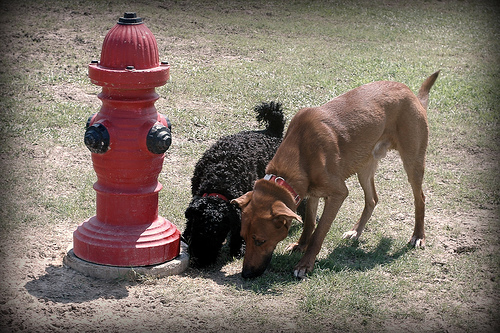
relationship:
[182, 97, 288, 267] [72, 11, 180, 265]
dog near hydrant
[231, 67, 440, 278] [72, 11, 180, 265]
dog near hydrant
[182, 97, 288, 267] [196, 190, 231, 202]
dog has collar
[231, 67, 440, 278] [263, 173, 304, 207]
dog has collar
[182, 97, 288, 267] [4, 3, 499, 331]
dog sniffing ground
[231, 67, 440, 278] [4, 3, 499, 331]
dog sniffing ground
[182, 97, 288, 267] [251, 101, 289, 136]
dog has tail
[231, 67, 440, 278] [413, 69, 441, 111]
dog has tail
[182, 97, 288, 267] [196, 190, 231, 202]
dog wearing collar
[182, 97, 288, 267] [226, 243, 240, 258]
dog has a paw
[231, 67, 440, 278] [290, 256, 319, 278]
dog has a paw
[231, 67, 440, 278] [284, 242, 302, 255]
dog has a paw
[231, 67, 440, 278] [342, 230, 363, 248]
dog has a paw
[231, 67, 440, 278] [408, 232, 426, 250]
dog has a paw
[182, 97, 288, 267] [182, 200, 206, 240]
dog has an ear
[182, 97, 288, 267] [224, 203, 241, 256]
dog has an ear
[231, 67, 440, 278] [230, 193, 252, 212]
dog has an ear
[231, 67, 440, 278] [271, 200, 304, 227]
dog has an ear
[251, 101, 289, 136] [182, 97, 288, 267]
tail of dog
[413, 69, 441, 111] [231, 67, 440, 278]
tail of dog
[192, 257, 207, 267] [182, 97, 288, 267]
nose of a dog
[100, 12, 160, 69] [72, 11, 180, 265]
top of hydrant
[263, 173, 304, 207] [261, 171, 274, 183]
collar has white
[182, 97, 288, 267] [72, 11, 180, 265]
dog next to hydrant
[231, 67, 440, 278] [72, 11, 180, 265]
dog next to hydrant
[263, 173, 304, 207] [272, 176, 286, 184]
collar has silver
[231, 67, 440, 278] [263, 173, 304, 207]
dog wearing collar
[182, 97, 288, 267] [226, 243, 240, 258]
dog has paw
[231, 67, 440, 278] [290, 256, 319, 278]
dog has paw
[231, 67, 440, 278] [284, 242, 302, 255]
dog has paw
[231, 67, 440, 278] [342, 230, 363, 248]
dog has paw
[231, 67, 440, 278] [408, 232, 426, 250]
dog has paw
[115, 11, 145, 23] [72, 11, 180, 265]
valve on hydrant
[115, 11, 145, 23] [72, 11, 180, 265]
valve on top of hydrant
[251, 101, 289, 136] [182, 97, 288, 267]
tail of canine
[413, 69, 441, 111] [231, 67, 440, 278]
tail of canine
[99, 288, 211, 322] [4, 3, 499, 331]
dirt on surface